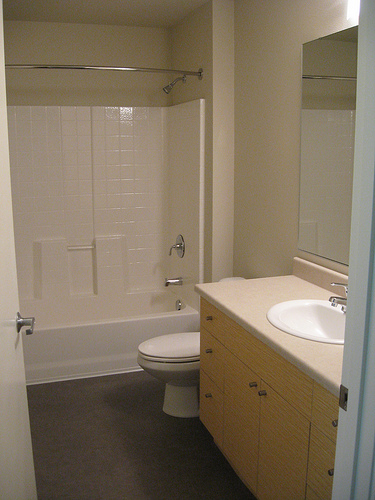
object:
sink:
[264, 296, 344, 345]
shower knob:
[168, 234, 186, 259]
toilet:
[135, 328, 203, 420]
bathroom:
[0, 0, 374, 499]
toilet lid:
[136, 329, 204, 358]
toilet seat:
[135, 326, 199, 364]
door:
[256, 379, 309, 497]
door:
[223, 348, 258, 495]